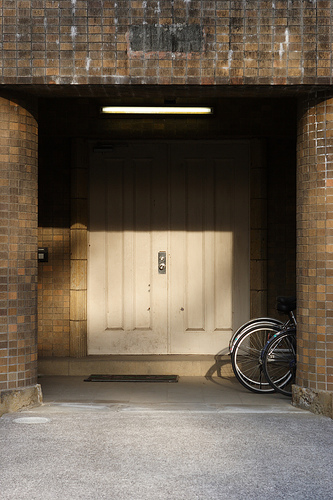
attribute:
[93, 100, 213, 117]
light — bright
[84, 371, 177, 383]
rug — black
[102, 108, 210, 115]
light — three foot, halogen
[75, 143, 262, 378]
door — beige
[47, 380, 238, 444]
platform — gray, concrete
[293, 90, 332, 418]
pillar — brown, brick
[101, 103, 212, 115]
light — bright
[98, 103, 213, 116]
outside light — bright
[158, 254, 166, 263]
lock — silver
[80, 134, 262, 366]
door — white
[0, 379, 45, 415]
base — cement, brick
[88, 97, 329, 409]
doors — white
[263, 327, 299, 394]
wheel — two or three, black, bicycle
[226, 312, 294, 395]
wheels — black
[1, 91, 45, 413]
support — brick, round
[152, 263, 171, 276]
doorknob — silver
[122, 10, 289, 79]
building — brick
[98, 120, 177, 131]
object — silver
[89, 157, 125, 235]
section — small